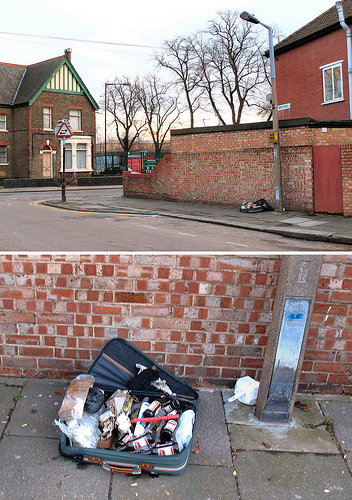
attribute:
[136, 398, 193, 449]
beer — brown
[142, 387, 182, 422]
bottle — dark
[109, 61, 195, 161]
tree — barren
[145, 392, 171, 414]
beer bottle — brown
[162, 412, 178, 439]
beer bottle — brown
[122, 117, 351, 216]
wall — brick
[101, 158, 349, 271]
sidewalk — grey, paved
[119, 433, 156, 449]
beer — brown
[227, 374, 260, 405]
bag — white, plastic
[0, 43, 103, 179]
house — brick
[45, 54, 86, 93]
trim — green, white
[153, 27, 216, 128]
tree — barren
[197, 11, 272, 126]
tree — barren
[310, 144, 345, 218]
gate — brown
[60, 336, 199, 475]
suitcase — open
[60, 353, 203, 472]
suitcase — open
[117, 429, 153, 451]
bottle — dark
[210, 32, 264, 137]
tree — barren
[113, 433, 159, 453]
bottle — dark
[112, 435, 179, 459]
beer bottle — brown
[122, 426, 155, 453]
bottle — brown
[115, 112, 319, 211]
brick wall — long, red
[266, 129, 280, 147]
sign — yellow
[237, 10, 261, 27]
lamp — street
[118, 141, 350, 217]
wall — brick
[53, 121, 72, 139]
sign — white, street